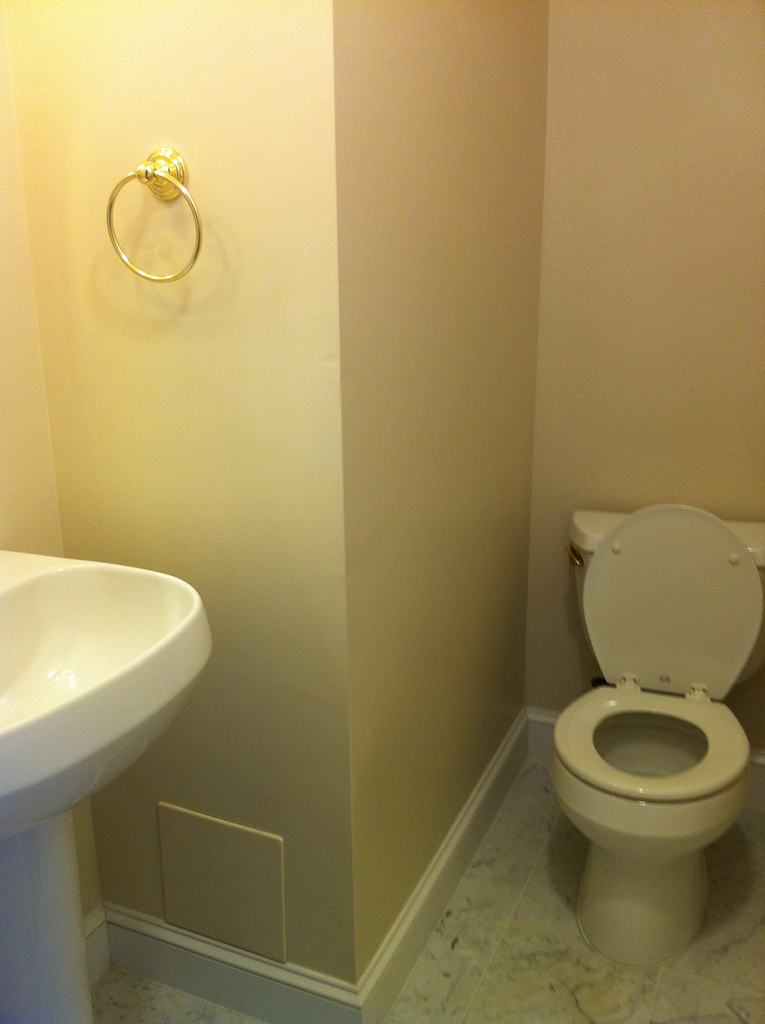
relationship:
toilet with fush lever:
[553, 484, 765, 971] [565, 544, 584, 566]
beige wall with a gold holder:
[34, 0, 341, 1023] [105, 147, 203, 284]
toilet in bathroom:
[547, 481, 762, 983] [17, 18, 747, 984]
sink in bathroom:
[6, 542, 224, 1021] [17, 18, 747, 984]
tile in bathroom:
[110, 699, 762, 1003] [17, 18, 747, 984]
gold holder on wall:
[105, 147, 203, 284] [34, 13, 326, 928]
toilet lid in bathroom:
[559, 468, 762, 716] [17, 18, 747, 984]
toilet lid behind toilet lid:
[583, 501, 765, 699] [580, 502, 759, 691]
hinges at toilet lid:
[608, 663, 755, 721] [609, 531, 759, 696]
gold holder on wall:
[102, 141, 211, 303] [34, 13, 326, 928]